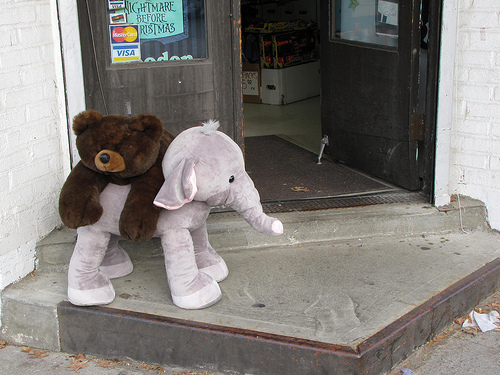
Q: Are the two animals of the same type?
A: No, they are bears and elephants.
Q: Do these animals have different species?
A: Yes, they are bears and elephants.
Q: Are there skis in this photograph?
A: No, there are no skis.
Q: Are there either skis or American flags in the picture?
A: No, there are no skis or American flags.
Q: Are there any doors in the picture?
A: Yes, there is a door.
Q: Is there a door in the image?
A: Yes, there is a door.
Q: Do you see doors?
A: Yes, there is a door.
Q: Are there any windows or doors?
A: Yes, there is a door.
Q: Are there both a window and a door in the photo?
A: Yes, there are both a door and a window.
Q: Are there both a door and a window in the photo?
A: Yes, there are both a door and a window.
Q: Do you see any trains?
A: No, there are no trains.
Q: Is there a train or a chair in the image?
A: No, there are no trains or chairs.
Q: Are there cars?
A: No, there are no cars.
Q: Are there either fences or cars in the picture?
A: No, there are no cars or fences.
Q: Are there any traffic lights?
A: No, there are no traffic lights.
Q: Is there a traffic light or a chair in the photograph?
A: No, there are no traffic lights or chairs.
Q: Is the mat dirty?
A: Yes, the mat is dirty.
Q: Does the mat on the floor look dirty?
A: Yes, the mat is dirty.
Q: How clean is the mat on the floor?
A: The mat is dirty.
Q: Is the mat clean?
A: No, the mat is dirty.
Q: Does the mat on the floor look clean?
A: No, the mat is dirty.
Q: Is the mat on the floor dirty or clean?
A: The mat is dirty.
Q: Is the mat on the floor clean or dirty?
A: The mat is dirty.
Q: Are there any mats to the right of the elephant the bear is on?
A: Yes, there is a mat to the right of the elephant.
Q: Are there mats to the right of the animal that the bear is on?
A: Yes, there is a mat to the right of the elephant.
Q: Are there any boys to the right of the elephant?
A: No, there is a mat to the right of the elephant.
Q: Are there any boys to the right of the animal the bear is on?
A: No, there is a mat to the right of the elephant.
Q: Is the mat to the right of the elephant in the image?
A: Yes, the mat is to the right of the elephant.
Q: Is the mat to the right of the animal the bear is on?
A: Yes, the mat is to the right of the elephant.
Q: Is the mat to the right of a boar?
A: No, the mat is to the right of the elephant.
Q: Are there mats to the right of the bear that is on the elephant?
A: Yes, there is a mat to the right of the bear.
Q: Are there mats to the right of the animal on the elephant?
A: Yes, there is a mat to the right of the bear.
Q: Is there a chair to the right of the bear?
A: No, there is a mat to the right of the bear.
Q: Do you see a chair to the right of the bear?
A: No, there is a mat to the right of the bear.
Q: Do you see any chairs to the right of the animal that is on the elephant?
A: No, there is a mat to the right of the bear.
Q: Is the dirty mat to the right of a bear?
A: Yes, the mat is to the right of a bear.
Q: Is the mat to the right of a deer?
A: No, the mat is to the right of a bear.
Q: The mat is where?
A: The mat is on the floor.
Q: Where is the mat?
A: The mat is on the floor.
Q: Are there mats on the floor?
A: Yes, there is a mat on the floor.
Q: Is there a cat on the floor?
A: No, there is a mat on the floor.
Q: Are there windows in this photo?
A: Yes, there is a window.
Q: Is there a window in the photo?
A: Yes, there is a window.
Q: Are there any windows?
A: Yes, there is a window.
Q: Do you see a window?
A: Yes, there is a window.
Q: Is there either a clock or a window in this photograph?
A: Yes, there is a window.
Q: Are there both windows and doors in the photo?
A: Yes, there are both a window and a door.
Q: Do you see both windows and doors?
A: Yes, there are both a window and a door.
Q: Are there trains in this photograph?
A: No, there are no trains.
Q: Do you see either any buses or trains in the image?
A: No, there are no trains or buses.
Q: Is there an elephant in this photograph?
A: Yes, there is an elephant.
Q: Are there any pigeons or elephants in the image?
A: Yes, there is an elephant.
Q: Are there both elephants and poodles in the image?
A: No, there is an elephant but no poodles.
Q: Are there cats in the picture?
A: No, there are no cats.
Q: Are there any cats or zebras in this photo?
A: No, there are no cats or zebras.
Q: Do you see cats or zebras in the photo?
A: No, there are no cats or zebras.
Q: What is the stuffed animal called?
A: The animal is an elephant.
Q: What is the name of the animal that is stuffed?
A: The animal is an elephant.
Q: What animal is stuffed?
A: The animal is an elephant.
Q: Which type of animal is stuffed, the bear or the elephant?
A: The elephant is stuffed.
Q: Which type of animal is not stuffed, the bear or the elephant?
A: The bear is not stuffed.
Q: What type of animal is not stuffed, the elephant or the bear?
A: The bear is not stuffed.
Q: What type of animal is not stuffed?
A: The animal is a bear.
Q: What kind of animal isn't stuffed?
A: The animal is a bear.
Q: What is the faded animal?
A: The animal is an elephant.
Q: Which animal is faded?
A: The animal is an elephant.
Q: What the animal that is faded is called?
A: The animal is an elephant.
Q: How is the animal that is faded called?
A: The animal is an elephant.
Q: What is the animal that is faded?
A: The animal is an elephant.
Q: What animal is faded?
A: The animal is an elephant.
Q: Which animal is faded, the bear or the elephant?
A: The elephant is faded.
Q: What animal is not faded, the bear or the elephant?
A: The bear is not faded.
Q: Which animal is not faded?
A: The animal is a bear.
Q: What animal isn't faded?
A: The animal is a bear.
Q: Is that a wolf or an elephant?
A: That is an elephant.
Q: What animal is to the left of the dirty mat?
A: The animal is an elephant.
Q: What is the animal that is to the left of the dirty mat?
A: The animal is an elephant.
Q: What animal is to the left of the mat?
A: The animal is an elephant.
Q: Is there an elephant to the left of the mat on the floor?
A: Yes, there is an elephant to the left of the mat.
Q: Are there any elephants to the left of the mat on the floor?
A: Yes, there is an elephant to the left of the mat.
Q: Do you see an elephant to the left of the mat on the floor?
A: Yes, there is an elephant to the left of the mat.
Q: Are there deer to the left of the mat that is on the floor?
A: No, there is an elephant to the left of the mat.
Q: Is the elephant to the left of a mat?
A: Yes, the elephant is to the left of a mat.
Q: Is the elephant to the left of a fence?
A: No, the elephant is to the left of a mat.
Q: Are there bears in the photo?
A: Yes, there is a bear.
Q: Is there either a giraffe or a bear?
A: Yes, there is a bear.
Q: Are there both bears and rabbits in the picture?
A: No, there is a bear but no rabbits.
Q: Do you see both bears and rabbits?
A: No, there is a bear but no rabbits.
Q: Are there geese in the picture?
A: No, there are no geese.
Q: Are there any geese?
A: No, there are no geese.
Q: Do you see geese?
A: No, there are no geese.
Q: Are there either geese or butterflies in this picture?
A: No, there are no geese or butterflies.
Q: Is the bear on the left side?
A: Yes, the bear is on the left of the image.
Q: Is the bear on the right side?
A: No, the bear is on the left of the image.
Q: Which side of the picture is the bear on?
A: The bear is on the left of the image.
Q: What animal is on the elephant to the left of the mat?
A: The bear is on the elephant.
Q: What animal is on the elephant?
A: The bear is on the elephant.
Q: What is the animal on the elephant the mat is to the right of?
A: The animal is a bear.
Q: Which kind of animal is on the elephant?
A: The animal is a bear.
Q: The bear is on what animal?
A: The bear is on the elephant.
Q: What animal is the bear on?
A: The bear is on the elephant.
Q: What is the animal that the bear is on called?
A: The animal is an elephant.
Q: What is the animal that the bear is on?
A: The animal is an elephant.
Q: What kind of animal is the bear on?
A: The bear is on the elephant.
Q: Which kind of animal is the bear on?
A: The bear is on the elephant.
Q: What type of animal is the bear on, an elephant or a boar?
A: The bear is on an elephant.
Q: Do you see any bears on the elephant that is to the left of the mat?
A: Yes, there is a bear on the elephant.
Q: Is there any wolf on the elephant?
A: No, there is a bear on the elephant.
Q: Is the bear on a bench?
A: No, the bear is on an elephant.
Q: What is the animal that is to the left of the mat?
A: The animal is a bear.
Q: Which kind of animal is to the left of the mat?
A: The animal is a bear.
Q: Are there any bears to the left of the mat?
A: Yes, there is a bear to the left of the mat.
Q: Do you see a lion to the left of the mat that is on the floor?
A: No, there is a bear to the left of the mat.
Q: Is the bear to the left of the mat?
A: Yes, the bear is to the left of the mat.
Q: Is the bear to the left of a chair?
A: No, the bear is to the left of the mat.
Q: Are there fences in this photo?
A: No, there are no fences.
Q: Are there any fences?
A: No, there are no fences.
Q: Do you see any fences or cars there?
A: No, there are no fences or cars.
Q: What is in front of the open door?
A: The steps are in front of the door.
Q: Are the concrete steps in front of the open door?
A: Yes, the steps are in front of the door.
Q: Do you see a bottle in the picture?
A: No, there are no bottles.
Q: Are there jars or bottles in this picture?
A: No, there are no bottles or jars.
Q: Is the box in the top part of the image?
A: Yes, the box is in the top of the image.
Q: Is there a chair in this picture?
A: No, there are no chairs.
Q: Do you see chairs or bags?
A: No, there are no chairs or bags.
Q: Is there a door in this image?
A: Yes, there is a door.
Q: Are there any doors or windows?
A: Yes, there is a door.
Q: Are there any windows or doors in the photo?
A: Yes, there is a door.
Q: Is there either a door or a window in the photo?
A: Yes, there is a door.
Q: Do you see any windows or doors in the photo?
A: Yes, there is a door.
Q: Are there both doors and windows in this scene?
A: Yes, there are both a door and a window.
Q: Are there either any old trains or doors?
A: Yes, there is an old door.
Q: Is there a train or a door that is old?
A: Yes, the door is old.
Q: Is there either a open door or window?
A: Yes, there is an open door.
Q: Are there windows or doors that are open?
A: Yes, the door is open.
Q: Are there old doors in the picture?
A: Yes, there is an old door.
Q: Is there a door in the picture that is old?
A: Yes, there is a door that is old.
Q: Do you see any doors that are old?
A: Yes, there is a door that is old.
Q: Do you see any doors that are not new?
A: Yes, there is a old door.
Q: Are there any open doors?
A: Yes, there is an open door.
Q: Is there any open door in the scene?
A: Yes, there is an open door.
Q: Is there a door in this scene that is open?
A: Yes, there is a door that is open.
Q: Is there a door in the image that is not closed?
A: Yes, there is a open door.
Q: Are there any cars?
A: No, there are no cars.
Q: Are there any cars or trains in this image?
A: No, there are no cars or trains.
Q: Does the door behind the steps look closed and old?
A: No, the door is old but open.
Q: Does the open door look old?
A: Yes, the door is old.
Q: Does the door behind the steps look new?
A: No, the door is old.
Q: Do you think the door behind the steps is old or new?
A: The door is old.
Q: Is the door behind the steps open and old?
A: Yes, the door is open and old.